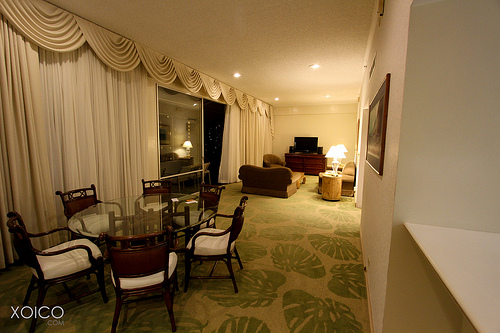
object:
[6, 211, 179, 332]
chairs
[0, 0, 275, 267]
curtain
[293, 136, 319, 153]
tv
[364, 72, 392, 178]
picture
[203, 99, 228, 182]
window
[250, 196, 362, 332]
floor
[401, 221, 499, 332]
counter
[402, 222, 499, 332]
inset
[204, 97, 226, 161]
sky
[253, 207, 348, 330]
pattern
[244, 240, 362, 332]
carpet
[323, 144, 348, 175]
lamps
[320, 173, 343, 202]
side table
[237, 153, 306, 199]
sofa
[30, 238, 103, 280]
cushion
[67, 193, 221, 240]
table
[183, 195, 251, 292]
chair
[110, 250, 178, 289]
seat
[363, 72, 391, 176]
painting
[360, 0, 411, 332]
wall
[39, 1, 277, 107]
valance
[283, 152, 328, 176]
chest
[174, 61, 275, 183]
curtains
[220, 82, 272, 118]
draping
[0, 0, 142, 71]
curtains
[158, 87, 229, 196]
windows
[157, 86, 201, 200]
window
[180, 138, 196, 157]
lamp reflection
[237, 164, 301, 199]
couch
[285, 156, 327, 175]
drawers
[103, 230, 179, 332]
chair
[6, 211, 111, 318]
chair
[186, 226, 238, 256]
cushion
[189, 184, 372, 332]
carpet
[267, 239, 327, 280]
design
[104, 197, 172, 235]
top